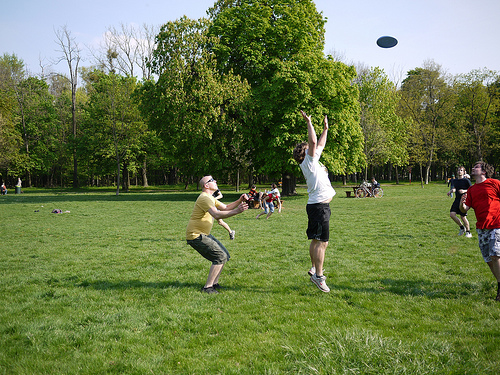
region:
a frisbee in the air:
[360, 24, 406, 70]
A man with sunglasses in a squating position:
[158, 137, 264, 297]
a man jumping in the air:
[285, 99, 362, 311]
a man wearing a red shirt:
[430, 146, 498, 296]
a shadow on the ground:
[327, 237, 465, 328]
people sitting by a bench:
[339, 167, 392, 209]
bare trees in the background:
[32, 20, 153, 204]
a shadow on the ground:
[47, 263, 206, 315]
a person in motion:
[252, 181, 287, 233]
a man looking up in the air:
[426, 153, 477, 251]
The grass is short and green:
[16, 290, 484, 370]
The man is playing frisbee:
[176, 172, 253, 295]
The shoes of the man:
[301, 263, 334, 297]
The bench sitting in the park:
[343, 171, 388, 201]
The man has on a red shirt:
[456, 175, 498, 235]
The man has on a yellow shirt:
[178, 190, 223, 244]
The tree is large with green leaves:
[192, 0, 366, 197]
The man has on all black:
[445, 162, 475, 238]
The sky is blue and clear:
[7, 1, 147, 46]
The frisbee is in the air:
[366, 28, 405, 53]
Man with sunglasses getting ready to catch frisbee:
[185, 170, 250, 292]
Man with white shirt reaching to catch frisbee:
[282, 105, 339, 295]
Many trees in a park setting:
[18, 58, 284, 175]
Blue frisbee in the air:
[359, 19, 414, 56]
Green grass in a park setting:
[26, 237, 187, 367]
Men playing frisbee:
[176, 102, 498, 304]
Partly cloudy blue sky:
[6, 6, 178, 57]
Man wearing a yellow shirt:
[183, 168, 249, 301]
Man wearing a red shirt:
[463, 155, 493, 267]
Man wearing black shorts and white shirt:
[279, 108, 366, 298]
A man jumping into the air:
[290, 106, 335, 293]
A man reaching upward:
[293, 107, 333, 296]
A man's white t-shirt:
[298, 145, 336, 203]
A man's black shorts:
[304, 202, 332, 242]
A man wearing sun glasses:
[196, 173, 219, 190]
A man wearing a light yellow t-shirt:
[185, 192, 226, 237]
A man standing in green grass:
[184, 175, 248, 318]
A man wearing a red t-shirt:
[466, 180, 498, 232]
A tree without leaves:
[51, 20, 84, 191]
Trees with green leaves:
[156, 3, 365, 193]